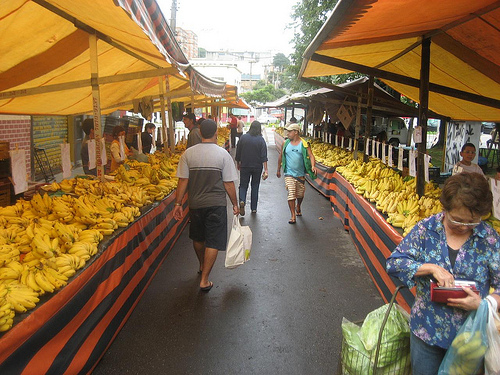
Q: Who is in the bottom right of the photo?
A: A women.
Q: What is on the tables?
A: Bananas.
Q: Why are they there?
A: To buy bananas.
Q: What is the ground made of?
A: Concrete.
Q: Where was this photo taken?
A: An outside market.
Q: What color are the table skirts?
A: Blue and orange.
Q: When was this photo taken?
A: Daytime.